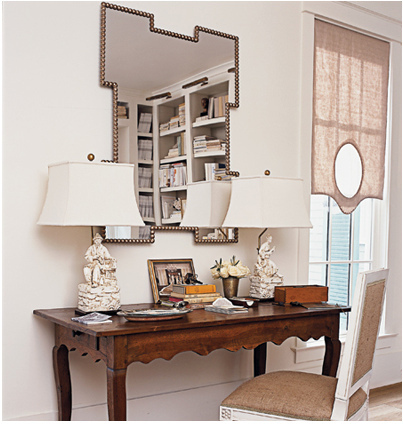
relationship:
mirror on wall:
[96, 1, 239, 247] [1, 2, 308, 424]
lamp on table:
[39, 151, 146, 313] [34, 303, 353, 423]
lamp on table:
[225, 175, 314, 306] [34, 303, 353, 423]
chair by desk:
[221, 270, 390, 421] [34, 303, 353, 423]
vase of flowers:
[208, 255, 247, 301] [205, 256, 249, 277]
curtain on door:
[310, 17, 389, 218] [300, 4, 403, 399]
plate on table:
[120, 300, 197, 323] [34, 303, 353, 423]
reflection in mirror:
[123, 75, 228, 243] [96, 1, 239, 247]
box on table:
[277, 284, 328, 306] [34, 303, 353, 423]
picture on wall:
[145, 259, 200, 305] [1, 2, 308, 424]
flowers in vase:
[205, 256, 249, 277] [208, 255, 247, 301]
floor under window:
[358, 381, 398, 421] [314, 11, 389, 344]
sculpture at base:
[72, 231, 125, 320] [79, 238, 116, 308]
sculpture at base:
[248, 231, 283, 299] [253, 233, 288, 307]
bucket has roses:
[224, 275, 243, 294] [205, 256, 249, 277]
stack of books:
[171, 280, 214, 307] [169, 283, 215, 317]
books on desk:
[169, 283, 215, 317] [34, 303, 353, 423]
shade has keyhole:
[310, 17, 389, 218] [333, 138, 363, 203]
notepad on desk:
[74, 310, 111, 325] [34, 303, 353, 423]